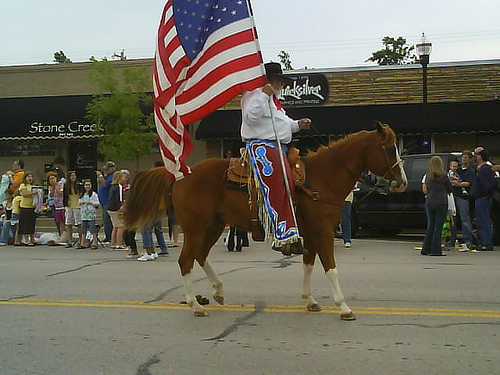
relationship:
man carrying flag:
[233, 55, 287, 227] [162, 5, 253, 115]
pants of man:
[239, 152, 296, 227] [233, 55, 287, 227]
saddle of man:
[224, 159, 245, 181] [233, 55, 287, 227]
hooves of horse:
[204, 291, 226, 305] [147, 160, 346, 257]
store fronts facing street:
[326, 73, 469, 128] [2, 249, 75, 269]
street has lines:
[2, 249, 75, 269] [74, 283, 145, 318]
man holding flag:
[233, 55, 287, 227] [162, 5, 253, 115]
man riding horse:
[233, 55, 287, 227] [147, 160, 346, 257]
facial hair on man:
[266, 84, 284, 92] [233, 55, 287, 227]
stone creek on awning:
[30, 123, 101, 136] [0, 108, 22, 141]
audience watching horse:
[2, 170, 96, 234] [147, 160, 346, 257]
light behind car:
[406, 69, 433, 93] [389, 214, 415, 237]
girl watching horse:
[78, 181, 99, 238] [147, 160, 346, 257]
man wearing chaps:
[233, 55, 287, 227] [261, 181, 306, 243]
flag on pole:
[162, 5, 253, 115] [404, 62, 434, 86]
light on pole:
[406, 69, 433, 93] [404, 62, 434, 86]